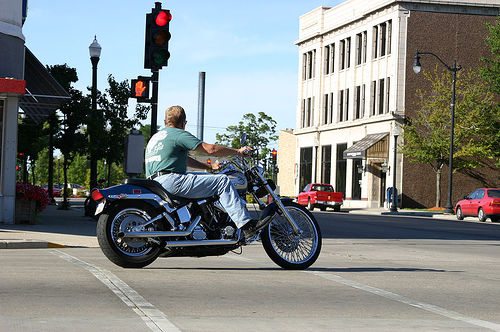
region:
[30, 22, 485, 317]
A man is riding a motorcycle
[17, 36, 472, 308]
A man is riding through a city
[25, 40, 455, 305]
A motorcyclist is not wearing a helmet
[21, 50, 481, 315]
A motorcyclist is at an intersection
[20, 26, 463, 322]
A motorcyclist is watching for traffic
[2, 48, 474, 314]
A motorcyclist is driving very carefully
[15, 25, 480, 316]
A motorcyclist is casting a shadow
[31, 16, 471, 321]
A motorcyclist is out in daytime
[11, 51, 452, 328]
A motorcyclist is at a street corner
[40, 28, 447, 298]
A motorcyclist is enjoying the day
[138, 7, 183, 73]
Red stop light on light pole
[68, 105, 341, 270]
Man on motorcylce on street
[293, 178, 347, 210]
Red pick up truck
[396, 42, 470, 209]
Tall lamp post on street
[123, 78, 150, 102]
Hand up for no walking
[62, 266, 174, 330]
White line on street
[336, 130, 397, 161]
Awning hanging over door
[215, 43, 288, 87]
Blue sky above building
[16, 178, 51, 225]
Flowering bush on sidewalk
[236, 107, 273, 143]
Green trees at the end of the street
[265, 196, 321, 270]
The front tire is black.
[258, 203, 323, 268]
The front tire is round.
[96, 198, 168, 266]
The back tire is black.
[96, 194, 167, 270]
The back tire is round.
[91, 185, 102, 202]
The rear light is red.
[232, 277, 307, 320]
The pavement is dark in color.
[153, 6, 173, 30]
The stop light is red.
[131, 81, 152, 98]
The light symbol is a hand.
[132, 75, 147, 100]
The hand is orange in color.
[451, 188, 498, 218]
The car on the right is red.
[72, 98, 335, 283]
An older man in the foreground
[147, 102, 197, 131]
Man's head is turned away from the camera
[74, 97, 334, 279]
Man is on a motorcycle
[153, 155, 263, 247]
Man is wearing pale blue jeans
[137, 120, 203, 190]
Man is wearing a green shirt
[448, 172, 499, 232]
A red sedan is parked on the street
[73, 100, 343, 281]
Motorcycle is on a crosswalk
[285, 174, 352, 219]
A red truck in the background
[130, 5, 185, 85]
A black traffic light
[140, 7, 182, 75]
Traffic light is on red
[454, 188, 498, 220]
a red compact car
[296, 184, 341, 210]
a red pick up truck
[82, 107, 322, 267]
a man riding a motorcycle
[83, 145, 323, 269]
a blue and white motorcycle with chrome accents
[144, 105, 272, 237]
a man wearing a green shirt and jeans riding a motorcycle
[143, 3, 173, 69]
a traffic signal with the red light illuminated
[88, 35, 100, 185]
a street light that is not on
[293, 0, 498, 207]
a brick building with many windows on the front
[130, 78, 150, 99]
a traffic signal with the red "do not walk" hand illuminated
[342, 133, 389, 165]
a brown awning